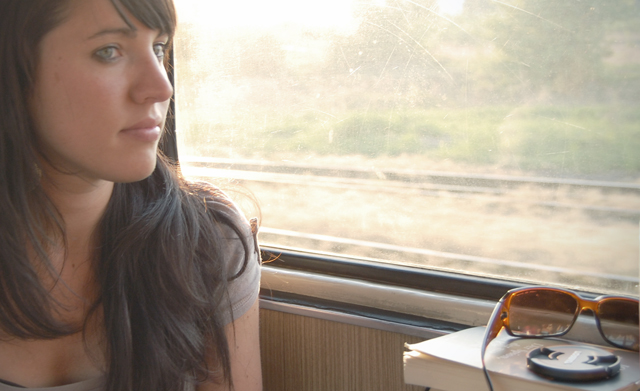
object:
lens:
[602, 297, 620, 343]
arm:
[475, 298, 504, 389]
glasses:
[483, 286, 640, 390]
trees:
[226, 10, 627, 174]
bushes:
[230, 95, 639, 181]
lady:
[0, 1, 253, 388]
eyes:
[89, 45, 127, 65]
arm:
[173, 193, 268, 389]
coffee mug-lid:
[524, 340, 622, 382]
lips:
[97, 115, 186, 149]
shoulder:
[55, 167, 323, 317]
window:
[160, 16, 639, 285]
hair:
[51, 114, 308, 379]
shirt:
[37, 229, 298, 357]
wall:
[255, 302, 421, 389]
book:
[401, 311, 640, 391]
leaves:
[511, 22, 590, 126]